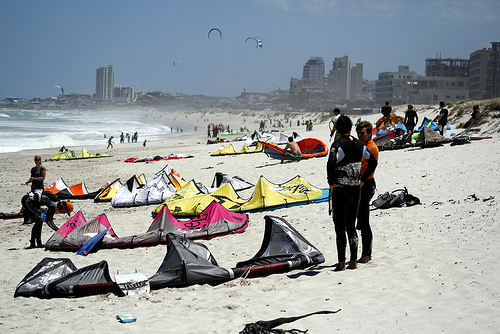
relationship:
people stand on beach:
[327, 116, 378, 271] [33, 114, 457, 331]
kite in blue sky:
[243, 32, 267, 57] [1, 0, 500, 100]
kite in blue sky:
[203, 23, 225, 44] [1, 0, 500, 100]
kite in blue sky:
[169, 59, 185, 73] [1, 0, 500, 100]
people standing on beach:
[327, 116, 378, 271] [15, 125, 486, 330]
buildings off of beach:
[229, 60, 453, 124] [169, 120, 491, 275]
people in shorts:
[280, 137, 302, 164] [282, 149, 302, 159]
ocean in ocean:
[0, 114, 174, 153] [0, 114, 174, 153]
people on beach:
[377, 97, 483, 133] [1, 103, 497, 332]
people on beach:
[317, 114, 386, 272] [1, 103, 497, 332]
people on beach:
[0, 156, 74, 248] [1, 103, 497, 332]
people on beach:
[21, 155, 46, 190] [49, 116, 496, 328]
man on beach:
[21, 191, 73, 248] [49, 116, 496, 328]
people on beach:
[327, 116, 378, 271] [49, 116, 496, 328]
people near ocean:
[87, 124, 157, 158] [0, 105, 175, 155]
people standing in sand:
[327, 116, 378, 271] [2, 98, 498, 330]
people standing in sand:
[21, 155, 46, 190] [2, 98, 498, 330]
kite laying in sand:
[151, 174, 332, 219] [2, 98, 498, 330]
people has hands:
[327, 116, 378, 271] [326, 140, 339, 190]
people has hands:
[327, 116, 378, 271] [358, 142, 378, 182]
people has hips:
[327, 116, 378, 271] [327, 170, 366, 198]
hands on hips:
[326, 140, 339, 190] [327, 170, 366, 198]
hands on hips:
[358, 142, 378, 182] [327, 170, 366, 198]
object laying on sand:
[117, 312, 138, 323] [2, 98, 498, 330]